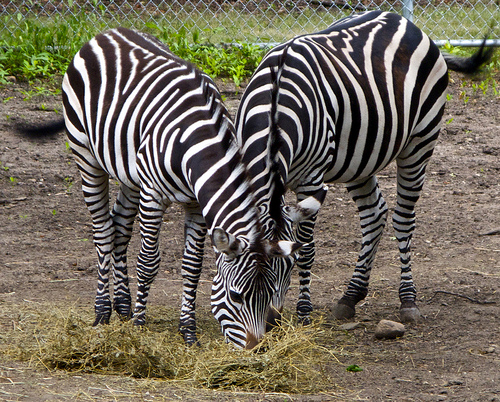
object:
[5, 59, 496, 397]
dirt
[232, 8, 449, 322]
zebra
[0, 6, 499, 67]
grass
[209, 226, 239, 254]
ear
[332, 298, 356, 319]
hoof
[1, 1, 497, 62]
fence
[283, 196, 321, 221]
ear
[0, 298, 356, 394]
grass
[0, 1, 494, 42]
chain fence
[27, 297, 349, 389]
hay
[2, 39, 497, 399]
ground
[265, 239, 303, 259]
ears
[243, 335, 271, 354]
nose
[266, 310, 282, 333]
nose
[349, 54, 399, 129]
strips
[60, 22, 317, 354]
zebra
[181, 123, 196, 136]
stripes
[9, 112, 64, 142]
tail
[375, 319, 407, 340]
brown rock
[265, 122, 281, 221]
mane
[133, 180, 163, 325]
leg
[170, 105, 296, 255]
neck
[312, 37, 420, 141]
stripe fur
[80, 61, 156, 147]
stripe fur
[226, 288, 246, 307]
eye